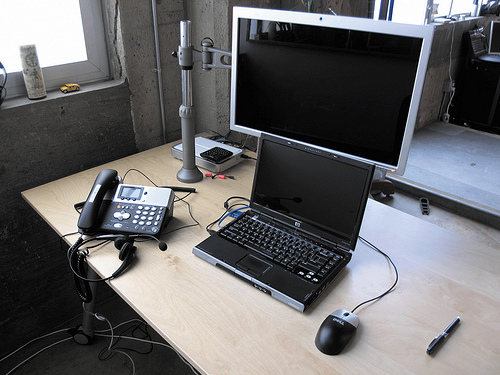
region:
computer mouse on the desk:
[312, 307, 361, 361]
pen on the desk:
[419, 314, 468, 356]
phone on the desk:
[76, 165, 176, 241]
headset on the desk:
[64, 234, 174, 288]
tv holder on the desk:
[168, 16, 234, 186]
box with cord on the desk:
[173, 134, 248, 177]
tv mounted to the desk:
[225, 6, 440, 181]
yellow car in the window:
[57, 80, 83, 95]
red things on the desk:
[204, 171, 234, 184]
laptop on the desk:
[191, 129, 381, 312]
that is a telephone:
[82, 158, 170, 235]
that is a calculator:
[200, 142, 231, 172]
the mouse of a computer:
[312, 311, 364, 346]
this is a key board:
[201, 215, 338, 296]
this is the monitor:
[264, 163, 358, 218]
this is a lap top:
[192, 141, 373, 303]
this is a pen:
[428, 316, 463, 356]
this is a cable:
[378, 276, 400, 297]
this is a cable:
[178, 202, 202, 233]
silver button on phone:
[133, 205, 145, 210]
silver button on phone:
[143, 205, 150, 210]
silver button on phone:
[149, 206, 156, 211]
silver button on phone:
[135, 207, 142, 214]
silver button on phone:
[141, 209, 149, 216]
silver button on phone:
[147, 209, 157, 214]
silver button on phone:
[133, 213, 141, 219]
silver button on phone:
[138, 214, 144, 221]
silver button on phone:
[146, 215, 152, 220]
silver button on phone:
[137, 218, 145, 226]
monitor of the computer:
[216, 0, 414, 171]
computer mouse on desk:
[317, 304, 356, 359]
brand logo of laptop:
[290, 214, 300, 229]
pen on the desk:
[426, 315, 466, 360]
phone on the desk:
[76, 165, 166, 238]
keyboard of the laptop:
[205, 217, 333, 307]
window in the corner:
[0, 26, 111, 83]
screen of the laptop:
[245, 150, 351, 238]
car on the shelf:
[46, 72, 86, 93]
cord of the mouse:
[352, 237, 392, 319]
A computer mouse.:
[311, 307, 362, 361]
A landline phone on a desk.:
[76, 166, 178, 231]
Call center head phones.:
[71, 232, 166, 280]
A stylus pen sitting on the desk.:
[423, 315, 461, 356]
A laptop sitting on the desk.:
[200, 135, 375, 310]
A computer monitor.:
[226, 16, 427, 176]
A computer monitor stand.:
[173, 18, 230, 187]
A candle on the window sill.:
[14, 45, 52, 97]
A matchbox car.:
[59, 83, 85, 95]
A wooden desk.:
[21, 126, 495, 371]